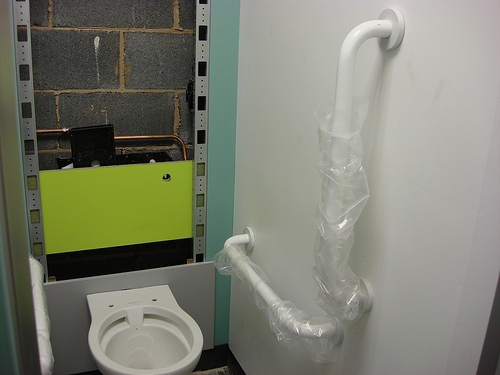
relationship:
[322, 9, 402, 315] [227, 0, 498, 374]
bar on wall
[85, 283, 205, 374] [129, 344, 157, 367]
toilet has water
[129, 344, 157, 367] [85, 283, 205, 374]
water in toilet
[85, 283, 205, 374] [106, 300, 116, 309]
toilet has lid hole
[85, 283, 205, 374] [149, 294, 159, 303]
toilet has lid hole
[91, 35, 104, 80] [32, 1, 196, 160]
paint on wall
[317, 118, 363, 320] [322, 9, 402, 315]
plastic on bar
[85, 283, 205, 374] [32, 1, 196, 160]
toilet against wall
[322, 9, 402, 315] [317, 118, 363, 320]
bar has plastic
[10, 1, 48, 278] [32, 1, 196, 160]
beam on wall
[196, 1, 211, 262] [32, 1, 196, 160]
beam on wall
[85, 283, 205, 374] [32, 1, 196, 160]
toilet on wall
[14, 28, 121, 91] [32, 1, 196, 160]
block on wall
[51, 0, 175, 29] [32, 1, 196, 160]
block on wall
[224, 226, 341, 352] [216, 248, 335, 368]
handle has plastic covering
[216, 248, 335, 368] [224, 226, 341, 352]
plastic covering on handle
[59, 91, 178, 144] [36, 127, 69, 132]
block near pipe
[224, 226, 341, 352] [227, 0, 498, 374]
handle on wall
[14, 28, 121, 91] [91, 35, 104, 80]
block has paint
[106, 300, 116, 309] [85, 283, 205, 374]
lid hole on back of toilet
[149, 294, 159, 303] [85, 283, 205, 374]
lid hole on back of toilet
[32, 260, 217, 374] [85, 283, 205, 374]
panel behind toilet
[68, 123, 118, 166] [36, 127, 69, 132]
panel in front of pipe